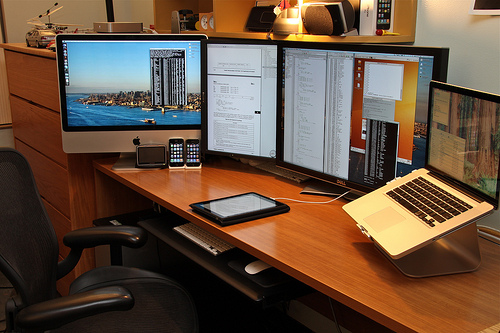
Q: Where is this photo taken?
A: In a room at a desk.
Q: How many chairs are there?
A: One.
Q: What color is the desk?
A: Brown.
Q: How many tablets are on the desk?
A: One.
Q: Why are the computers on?
A: Because the owner is still using them.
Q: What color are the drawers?
A: Brown.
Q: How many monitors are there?
A: Three.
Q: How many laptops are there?
A: One.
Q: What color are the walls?
A: White.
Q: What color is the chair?
A: Black.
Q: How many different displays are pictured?
A: Seven.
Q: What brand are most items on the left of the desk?
A: Apple.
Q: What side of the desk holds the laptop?
A: Right.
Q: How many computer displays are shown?
A: Four.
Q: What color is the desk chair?
A: Black.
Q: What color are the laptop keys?
A: Black.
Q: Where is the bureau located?
A: Left of desk.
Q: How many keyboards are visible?
A: Two.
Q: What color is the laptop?
A: Silver.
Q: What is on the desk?
A: Three monitors and one laptop.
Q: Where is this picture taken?
A: In an office.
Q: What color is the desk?
A: Brown.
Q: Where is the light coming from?
A: The computer screens.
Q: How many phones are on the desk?
A: Two.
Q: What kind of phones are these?
A: Iphones.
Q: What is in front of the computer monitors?
A: An ipad.